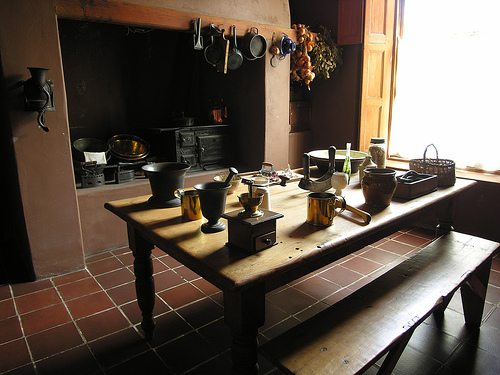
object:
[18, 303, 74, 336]
red tile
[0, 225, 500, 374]
ground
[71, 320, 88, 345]
grout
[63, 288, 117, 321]
tile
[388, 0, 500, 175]
window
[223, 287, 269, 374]
leg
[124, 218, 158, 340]
leg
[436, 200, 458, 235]
leg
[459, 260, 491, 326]
leg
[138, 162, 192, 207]
small/black bucket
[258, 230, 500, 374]
wooden bench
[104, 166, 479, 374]
table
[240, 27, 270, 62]
pan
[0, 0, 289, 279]
brown wall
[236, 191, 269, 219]
top